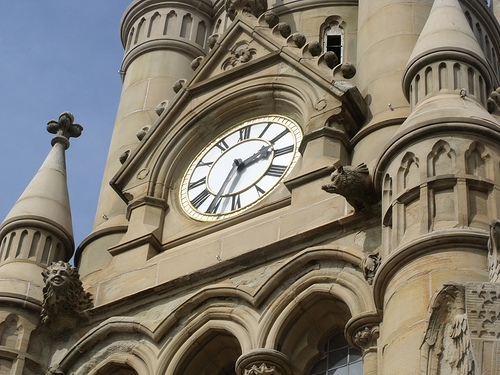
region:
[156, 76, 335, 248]
clock face with roman numerals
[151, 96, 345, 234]
circular clock reading 2:35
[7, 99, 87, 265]
stone tower with stone flower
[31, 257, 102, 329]
stone gargoyle on side of building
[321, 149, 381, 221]
animal gargoyle on side of building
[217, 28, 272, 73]
stone crab carving on building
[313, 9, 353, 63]
hidden window on stone building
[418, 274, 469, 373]
stone angel wing on building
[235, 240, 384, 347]
stone arch held up by pillars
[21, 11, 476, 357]
ornate stone building with clock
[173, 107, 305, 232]
A white clock on a building.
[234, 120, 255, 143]
Black numbers on a clock.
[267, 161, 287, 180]
Roman numeral numbers on a clock.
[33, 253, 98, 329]
Statue with a smiling face on a building.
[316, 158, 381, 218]
Statue of a wolf on a building.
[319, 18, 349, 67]
A tiny window on a building.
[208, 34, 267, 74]
Crab design on front of building.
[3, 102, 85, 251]
A cylinder cone shape on left side of building.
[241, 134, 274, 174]
Short hand on the clock.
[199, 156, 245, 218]
Long hand on the clock.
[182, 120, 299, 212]
white gold and black large clock face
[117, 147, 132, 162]
a stone flurish on the front of an old building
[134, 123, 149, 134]
a stone flurish on the front of an old building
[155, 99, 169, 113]
a stone flurish on the front of an old building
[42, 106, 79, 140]
a stone flurish on the front of an old building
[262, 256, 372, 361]
a stone archway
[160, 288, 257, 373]
a stone archway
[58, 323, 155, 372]
a stone archway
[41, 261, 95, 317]
a stone face sculpture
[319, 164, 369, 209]
a stone boar face sculpture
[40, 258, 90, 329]
A statuete figure with hair.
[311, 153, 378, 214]
A statue of an animal.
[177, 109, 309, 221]
A clock on the tower.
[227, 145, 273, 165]
Black hand of clock.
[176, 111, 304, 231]
Gold trim on the clock.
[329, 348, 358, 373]
A window on the tower.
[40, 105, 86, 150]
The top of the spire.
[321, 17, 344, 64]
A small window on tower.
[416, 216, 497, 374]
A eagle statue on the side.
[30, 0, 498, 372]
A clocltower with statues.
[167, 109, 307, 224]
face of a clock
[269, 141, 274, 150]
sharp point of a clock hand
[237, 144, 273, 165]
small black clock hand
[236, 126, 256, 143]
black roman numerals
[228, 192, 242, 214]
upside down roman numerals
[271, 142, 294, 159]
sideways roman numerals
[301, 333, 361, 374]
top of a window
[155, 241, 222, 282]
rectangular stone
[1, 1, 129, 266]
blue sky with no clouds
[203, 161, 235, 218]
long and thin clock hand